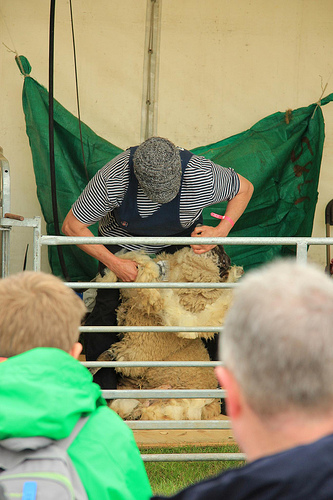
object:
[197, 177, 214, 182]
stripe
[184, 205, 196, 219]
stripe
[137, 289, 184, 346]
wool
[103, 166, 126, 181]
stripe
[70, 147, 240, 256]
shirt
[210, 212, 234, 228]
band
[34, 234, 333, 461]
bar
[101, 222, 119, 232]
stripe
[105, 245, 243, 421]
animal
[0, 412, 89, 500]
backpack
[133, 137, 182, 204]
cap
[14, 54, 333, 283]
fabric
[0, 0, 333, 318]
wall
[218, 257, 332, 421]
hair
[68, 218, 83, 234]
muscles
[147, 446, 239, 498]
ground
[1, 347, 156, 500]
jacket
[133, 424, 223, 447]
stone ground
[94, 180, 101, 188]
stripe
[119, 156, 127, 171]
stripe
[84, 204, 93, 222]
stripe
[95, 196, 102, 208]
stripe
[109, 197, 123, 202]
stripe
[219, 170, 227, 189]
stripe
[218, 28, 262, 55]
spots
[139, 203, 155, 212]
blue stripe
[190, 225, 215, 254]
hand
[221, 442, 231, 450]
stone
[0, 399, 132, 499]
back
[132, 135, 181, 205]
head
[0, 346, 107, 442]
hood